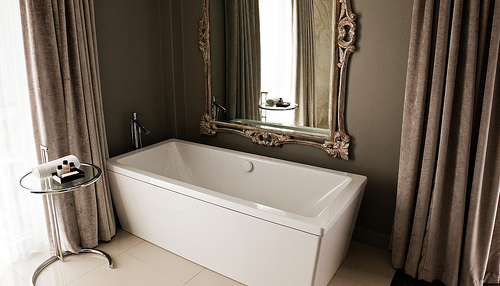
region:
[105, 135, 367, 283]
the large white bathtub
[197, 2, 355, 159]
the mirror on the wall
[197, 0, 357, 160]
the decorative frame around the mirror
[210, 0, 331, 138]
the reflection in the mirror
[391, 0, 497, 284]
the curtain hanging near the tub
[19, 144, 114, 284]
the small table near the tub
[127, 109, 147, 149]
the water faucet fixture on the tub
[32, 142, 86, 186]
the contents on the table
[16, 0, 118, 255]
the curtain hanging near the tub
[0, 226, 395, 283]
the light colored tiles on the floor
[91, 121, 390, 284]
The bathtub in a bathroom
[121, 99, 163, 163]
The faucet of a bathtub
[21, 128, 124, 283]
Bathtub accessories on a table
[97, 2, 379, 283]
A bathtub with a mirror above it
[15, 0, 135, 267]
Curtains in a bathroom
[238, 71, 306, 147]
The reflection of a bathroom table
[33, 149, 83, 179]
A white towel on a glass surfaced table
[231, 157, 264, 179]
The upper drain of a bathtub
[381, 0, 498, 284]
A bath curtain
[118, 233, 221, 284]
Floor tiling near a bathtub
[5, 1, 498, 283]
This is a bathroom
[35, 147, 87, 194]
Toiletries on end table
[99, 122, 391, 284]
This is a bathtub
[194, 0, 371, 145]
This is a mirror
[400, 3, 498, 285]
Long and tan curtain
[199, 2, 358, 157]
Golden frame on mirror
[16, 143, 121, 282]
Metal and glass table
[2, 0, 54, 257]
Window next to curtain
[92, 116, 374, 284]
The bathtub is white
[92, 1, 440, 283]
Olive green painted walls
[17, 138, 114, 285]
Small galss and chrome end table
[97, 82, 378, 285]
Small white bathtub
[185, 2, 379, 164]
Large mirror hanging on the wall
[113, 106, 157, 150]
Small silver fixture of the bathtub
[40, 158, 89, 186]
Small objects on the end table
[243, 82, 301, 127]
Small reflection in the mirror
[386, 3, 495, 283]
LOng brown drape hanging up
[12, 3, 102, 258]
LOng brown drape hanging up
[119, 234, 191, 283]
Large brown grout line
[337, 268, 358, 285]
Small brown grout line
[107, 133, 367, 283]
a white bathtub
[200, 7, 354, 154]
mirror above the bathtub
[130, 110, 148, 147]
metal bathtub fixture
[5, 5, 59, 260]
window on the left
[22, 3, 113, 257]
sand colored curtain on the left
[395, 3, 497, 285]
sand colored curtain on the right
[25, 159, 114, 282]
small table with a glass top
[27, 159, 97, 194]
round glass top on table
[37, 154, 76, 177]
small white towel on table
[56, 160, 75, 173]
small bottles of shampoo on table.